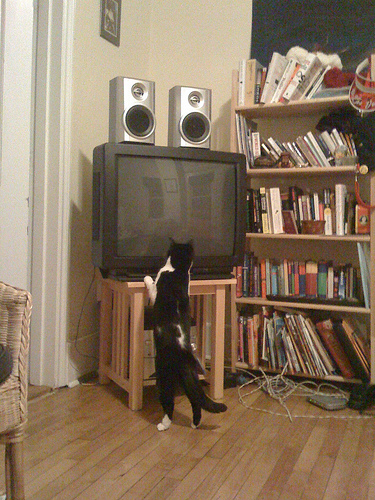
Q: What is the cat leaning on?
A: Table.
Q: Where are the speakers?
A: On Tv.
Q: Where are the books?
A: Bookshelf.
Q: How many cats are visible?
A: One.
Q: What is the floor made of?
A: Wood.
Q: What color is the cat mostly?
A: Black.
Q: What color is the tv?
A: Black.